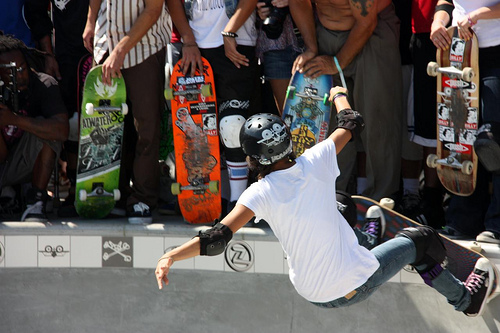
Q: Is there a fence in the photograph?
A: No, there are no fences.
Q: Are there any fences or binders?
A: No, there are no fences or binders.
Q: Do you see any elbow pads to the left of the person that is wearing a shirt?
A: Yes, there is an elbow pad to the left of the person.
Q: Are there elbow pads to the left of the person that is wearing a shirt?
A: Yes, there is an elbow pad to the left of the person.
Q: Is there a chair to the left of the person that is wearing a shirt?
A: No, there is an elbow pad to the left of the person.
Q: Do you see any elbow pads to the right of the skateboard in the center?
A: Yes, there is an elbow pad to the right of the skateboard.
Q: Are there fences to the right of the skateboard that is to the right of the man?
A: No, there is an elbow pad to the right of the skateboard.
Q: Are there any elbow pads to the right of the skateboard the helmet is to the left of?
A: Yes, there is an elbow pad to the right of the skateboard.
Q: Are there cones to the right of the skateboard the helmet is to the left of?
A: No, there is an elbow pad to the right of the skateboard.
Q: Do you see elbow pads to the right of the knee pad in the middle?
A: Yes, there is an elbow pad to the right of the knee pad.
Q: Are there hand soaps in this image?
A: No, there are no hand soaps.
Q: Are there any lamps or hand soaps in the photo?
A: No, there are no hand soaps or lamps.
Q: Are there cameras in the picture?
A: Yes, there is a camera.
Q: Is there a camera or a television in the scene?
A: Yes, there is a camera.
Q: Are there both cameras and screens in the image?
A: No, there is a camera but no screens.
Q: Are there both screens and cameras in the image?
A: No, there is a camera but no screens.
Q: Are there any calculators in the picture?
A: No, there are no calculators.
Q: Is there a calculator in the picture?
A: No, there are no calculators.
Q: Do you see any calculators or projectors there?
A: No, there are no calculators or projectors.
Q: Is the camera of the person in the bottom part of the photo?
A: No, the camera is in the top of the image.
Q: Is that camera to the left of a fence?
A: No, the camera is to the left of a person.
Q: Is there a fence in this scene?
A: No, there are no fences.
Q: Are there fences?
A: No, there are no fences.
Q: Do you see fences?
A: No, there are no fences.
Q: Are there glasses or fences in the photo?
A: No, there are no fences or glasses.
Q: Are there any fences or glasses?
A: No, there are no fences or glasses.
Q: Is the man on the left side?
A: Yes, the man is on the left of the image.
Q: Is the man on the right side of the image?
A: No, the man is on the left of the image.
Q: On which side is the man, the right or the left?
A: The man is on the left of the image.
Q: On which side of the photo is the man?
A: The man is on the left of the image.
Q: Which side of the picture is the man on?
A: The man is on the left of the image.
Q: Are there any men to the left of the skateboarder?
A: Yes, there is a man to the left of the skateboarder.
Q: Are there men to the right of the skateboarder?
A: No, the man is to the left of the skateboarder.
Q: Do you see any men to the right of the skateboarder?
A: No, the man is to the left of the skateboarder.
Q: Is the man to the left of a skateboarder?
A: Yes, the man is to the left of a skateboarder.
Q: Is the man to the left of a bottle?
A: No, the man is to the left of a skateboarder.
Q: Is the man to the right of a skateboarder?
A: No, the man is to the left of a skateboarder.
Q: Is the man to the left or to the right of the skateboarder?
A: The man is to the left of the skateboarder.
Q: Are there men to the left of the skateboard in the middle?
A: Yes, there is a man to the left of the skateboard.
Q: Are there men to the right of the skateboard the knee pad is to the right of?
A: No, the man is to the left of the skateboard.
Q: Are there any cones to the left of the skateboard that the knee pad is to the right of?
A: No, there is a man to the left of the skateboard.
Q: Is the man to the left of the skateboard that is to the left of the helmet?
A: Yes, the man is to the left of the skateboard.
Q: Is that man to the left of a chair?
A: No, the man is to the left of the skateboard.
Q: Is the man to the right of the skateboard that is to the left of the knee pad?
A: No, the man is to the left of the skateboard.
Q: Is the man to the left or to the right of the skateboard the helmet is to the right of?
A: The man is to the left of the skateboard.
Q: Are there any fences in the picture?
A: No, there are no fences.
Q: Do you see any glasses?
A: No, there are no glasses.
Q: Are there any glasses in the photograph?
A: No, there are no glasses.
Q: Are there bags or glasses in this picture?
A: No, there are no glasses or bags.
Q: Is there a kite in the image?
A: No, there are no kites.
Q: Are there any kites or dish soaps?
A: No, there are no kites or dish soaps.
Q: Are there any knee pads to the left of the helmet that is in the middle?
A: Yes, there is a knee pad to the left of the helmet.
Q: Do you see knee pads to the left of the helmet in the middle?
A: Yes, there is a knee pad to the left of the helmet.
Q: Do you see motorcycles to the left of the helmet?
A: No, there is a knee pad to the left of the helmet.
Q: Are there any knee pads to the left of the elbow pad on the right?
A: Yes, there is a knee pad to the left of the elbow pad.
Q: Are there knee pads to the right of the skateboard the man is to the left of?
A: Yes, there is a knee pad to the right of the skateboard.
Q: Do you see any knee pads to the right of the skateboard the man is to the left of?
A: Yes, there is a knee pad to the right of the skateboard.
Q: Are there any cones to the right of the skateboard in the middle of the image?
A: No, there is a knee pad to the right of the skateboard.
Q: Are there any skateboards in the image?
A: Yes, there is a skateboard.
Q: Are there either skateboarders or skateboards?
A: Yes, there is a skateboard.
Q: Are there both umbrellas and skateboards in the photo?
A: No, there is a skateboard but no umbrellas.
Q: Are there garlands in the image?
A: No, there are no garlands.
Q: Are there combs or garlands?
A: No, there are no garlands or combs.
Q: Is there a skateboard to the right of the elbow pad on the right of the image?
A: Yes, there is a skateboard to the right of the elbow pad.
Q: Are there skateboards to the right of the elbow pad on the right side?
A: Yes, there is a skateboard to the right of the elbow pad.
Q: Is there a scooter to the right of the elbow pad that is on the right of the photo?
A: No, there is a skateboard to the right of the elbow pad.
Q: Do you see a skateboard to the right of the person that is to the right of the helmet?
A: Yes, there is a skateboard to the right of the person.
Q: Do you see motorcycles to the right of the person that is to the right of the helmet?
A: No, there is a skateboard to the right of the person.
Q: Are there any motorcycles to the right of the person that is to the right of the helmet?
A: No, there is a skateboard to the right of the person.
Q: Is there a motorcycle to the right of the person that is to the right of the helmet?
A: No, there is a skateboard to the right of the person.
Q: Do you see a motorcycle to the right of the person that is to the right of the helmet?
A: No, there is a skateboard to the right of the person.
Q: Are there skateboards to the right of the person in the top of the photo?
A: Yes, there is a skateboard to the right of the person.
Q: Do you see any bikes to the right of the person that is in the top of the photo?
A: No, there is a skateboard to the right of the person.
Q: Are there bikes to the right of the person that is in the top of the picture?
A: No, there is a skateboard to the right of the person.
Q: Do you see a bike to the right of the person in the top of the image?
A: No, there is a skateboard to the right of the person.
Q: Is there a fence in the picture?
A: No, there are no fences.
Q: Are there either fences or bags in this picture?
A: No, there are no fences or bags.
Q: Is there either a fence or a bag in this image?
A: No, there are no fences or bags.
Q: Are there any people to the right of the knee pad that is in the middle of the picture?
A: Yes, there is a person to the right of the knee pad.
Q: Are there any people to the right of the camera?
A: Yes, there is a person to the right of the camera.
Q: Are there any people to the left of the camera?
A: No, the person is to the right of the camera.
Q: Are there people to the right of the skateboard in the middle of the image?
A: Yes, there is a person to the right of the skateboard.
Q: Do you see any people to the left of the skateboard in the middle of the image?
A: No, the person is to the right of the skateboard.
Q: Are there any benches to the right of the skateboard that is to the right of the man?
A: No, there is a person to the right of the skateboard.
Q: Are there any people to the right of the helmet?
A: Yes, there is a person to the right of the helmet.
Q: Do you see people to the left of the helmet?
A: No, the person is to the right of the helmet.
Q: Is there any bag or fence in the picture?
A: No, there are no fences or bags.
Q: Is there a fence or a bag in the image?
A: No, there are no fences or bags.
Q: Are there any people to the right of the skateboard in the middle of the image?
A: Yes, there is a person to the right of the skateboard.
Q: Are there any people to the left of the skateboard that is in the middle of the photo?
A: No, the person is to the right of the skateboard.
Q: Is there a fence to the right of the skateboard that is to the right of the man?
A: No, there is a person to the right of the skateboard.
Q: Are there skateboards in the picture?
A: Yes, there is a skateboard.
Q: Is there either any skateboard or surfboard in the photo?
A: Yes, there is a skateboard.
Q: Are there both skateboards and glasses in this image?
A: No, there is a skateboard but no glasses.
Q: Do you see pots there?
A: No, there are no pots.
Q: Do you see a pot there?
A: No, there are no pots.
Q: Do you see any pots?
A: No, there are no pots.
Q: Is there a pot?
A: No, there are no pots.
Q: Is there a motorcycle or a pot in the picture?
A: No, there are no pots or motorcycles.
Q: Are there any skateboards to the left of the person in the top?
A: Yes, there is a skateboard to the left of the person.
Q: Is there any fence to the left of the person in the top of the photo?
A: No, there is a skateboard to the left of the person.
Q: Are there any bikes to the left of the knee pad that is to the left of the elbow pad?
A: No, there is a skateboard to the left of the knee pad.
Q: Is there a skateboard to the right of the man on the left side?
A: Yes, there is a skateboard to the right of the man.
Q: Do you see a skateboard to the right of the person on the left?
A: Yes, there is a skateboard to the right of the man.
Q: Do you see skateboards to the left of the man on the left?
A: No, the skateboard is to the right of the man.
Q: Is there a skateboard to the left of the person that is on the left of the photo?
A: No, the skateboard is to the right of the man.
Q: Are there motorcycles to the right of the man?
A: No, there is a skateboard to the right of the man.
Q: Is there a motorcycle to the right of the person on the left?
A: No, there is a skateboard to the right of the man.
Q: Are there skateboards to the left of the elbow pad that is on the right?
A: Yes, there is a skateboard to the left of the elbow pad.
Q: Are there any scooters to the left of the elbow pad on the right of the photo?
A: No, there is a skateboard to the left of the elbow pad.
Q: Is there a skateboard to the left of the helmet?
A: Yes, there is a skateboard to the left of the helmet.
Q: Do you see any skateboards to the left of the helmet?
A: Yes, there is a skateboard to the left of the helmet.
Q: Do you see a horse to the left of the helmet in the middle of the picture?
A: No, there is a skateboard to the left of the helmet.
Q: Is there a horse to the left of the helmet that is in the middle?
A: No, there is a skateboard to the left of the helmet.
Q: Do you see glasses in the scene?
A: No, there are no glasses.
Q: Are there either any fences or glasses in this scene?
A: No, there are no glasses or fences.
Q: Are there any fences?
A: No, there are no fences.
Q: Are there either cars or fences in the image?
A: No, there are no fences or cars.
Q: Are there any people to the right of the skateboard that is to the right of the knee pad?
A: Yes, there is a person to the right of the skateboard.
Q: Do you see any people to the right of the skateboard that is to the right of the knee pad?
A: Yes, there is a person to the right of the skateboard.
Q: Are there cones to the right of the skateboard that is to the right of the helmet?
A: No, there is a person to the right of the skateboard.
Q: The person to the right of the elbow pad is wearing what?
A: The person is wearing a shirt.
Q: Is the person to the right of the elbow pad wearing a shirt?
A: Yes, the person is wearing a shirt.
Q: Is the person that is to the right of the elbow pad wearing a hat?
A: No, the person is wearing a shirt.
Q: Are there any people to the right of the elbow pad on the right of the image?
A: Yes, there is a person to the right of the elbow pad.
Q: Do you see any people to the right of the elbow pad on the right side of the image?
A: Yes, there is a person to the right of the elbow pad.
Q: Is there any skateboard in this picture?
A: Yes, there is a skateboard.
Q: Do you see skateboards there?
A: Yes, there is a skateboard.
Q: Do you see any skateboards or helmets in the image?
A: Yes, there is a skateboard.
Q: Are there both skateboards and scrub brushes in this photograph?
A: No, there is a skateboard but no scrub brushes.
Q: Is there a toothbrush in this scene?
A: No, there are no toothbrushes.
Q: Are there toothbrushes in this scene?
A: No, there are no toothbrushes.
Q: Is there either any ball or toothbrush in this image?
A: No, there are no toothbrushes or balls.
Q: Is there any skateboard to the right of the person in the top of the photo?
A: Yes, there is a skateboard to the right of the person.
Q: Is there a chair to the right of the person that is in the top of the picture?
A: No, there is a skateboard to the right of the person.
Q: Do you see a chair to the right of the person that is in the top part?
A: No, there is a skateboard to the right of the person.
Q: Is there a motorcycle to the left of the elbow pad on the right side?
A: No, there is a skateboard to the left of the elbow pad.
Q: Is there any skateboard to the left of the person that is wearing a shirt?
A: Yes, there is a skateboard to the left of the person.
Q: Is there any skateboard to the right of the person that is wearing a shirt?
A: No, the skateboard is to the left of the person.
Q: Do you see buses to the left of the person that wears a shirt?
A: No, there is a skateboard to the left of the person.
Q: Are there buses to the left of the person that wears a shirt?
A: No, there is a skateboard to the left of the person.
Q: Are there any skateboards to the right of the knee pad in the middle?
A: Yes, there is a skateboard to the right of the knee pad.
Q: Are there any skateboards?
A: Yes, there is a skateboard.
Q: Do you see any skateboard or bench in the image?
A: Yes, there is a skateboard.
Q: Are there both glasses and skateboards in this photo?
A: No, there is a skateboard but no glasses.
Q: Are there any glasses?
A: No, there are no glasses.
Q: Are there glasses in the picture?
A: No, there are no glasses.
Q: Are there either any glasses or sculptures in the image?
A: No, there are no glasses or sculptures.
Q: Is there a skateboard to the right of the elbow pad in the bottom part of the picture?
A: Yes, there is a skateboard to the right of the elbow pad.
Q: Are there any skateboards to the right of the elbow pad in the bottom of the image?
A: Yes, there is a skateboard to the right of the elbow pad.